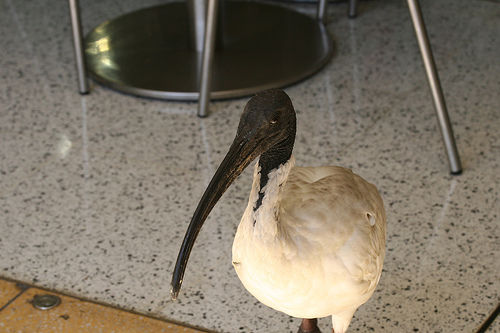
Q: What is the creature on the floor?
A: Bird.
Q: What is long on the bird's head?
A: Beak.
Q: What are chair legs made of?
A: Metal.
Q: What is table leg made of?
A: Metal.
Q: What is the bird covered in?
A: Feathers.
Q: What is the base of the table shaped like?
A: Circle.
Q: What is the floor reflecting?
A: Light.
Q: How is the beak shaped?
A: It is tapered downward.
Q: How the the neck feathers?
A: Slightly ruffled.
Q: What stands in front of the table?
A: A bird.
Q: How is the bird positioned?
A: Standing on two legs.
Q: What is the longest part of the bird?
A: Its black beak.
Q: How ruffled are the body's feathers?
A: Not at all.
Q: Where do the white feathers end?
A: At the neck and head.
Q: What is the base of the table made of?
A: Metal.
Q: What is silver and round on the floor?
A: Coin.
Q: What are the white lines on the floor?
A: Reflection of the chair legs.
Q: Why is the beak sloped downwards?
A: Shaped that way.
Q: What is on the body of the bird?
A: Feathers.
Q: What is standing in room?
A: Bird.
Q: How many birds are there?
A: One.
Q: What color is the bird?
A: White and brown.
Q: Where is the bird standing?
A: Floor.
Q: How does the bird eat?
A: Beak.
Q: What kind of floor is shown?
A: Tile.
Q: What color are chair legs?
A: Silver.